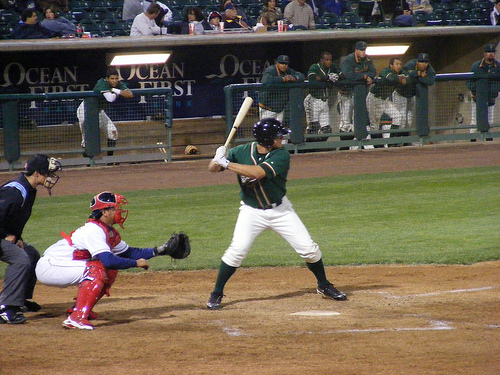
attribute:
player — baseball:
[250, 43, 296, 137]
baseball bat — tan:
[208, 88, 260, 178]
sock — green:
[213, 259, 231, 295]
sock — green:
[299, 264, 337, 294]